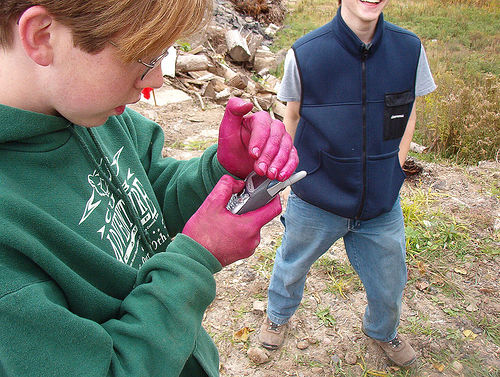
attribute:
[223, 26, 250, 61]
log — fallen